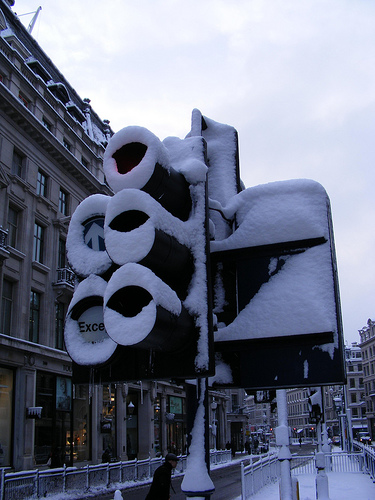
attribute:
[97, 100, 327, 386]
light — signal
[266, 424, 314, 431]
lights — red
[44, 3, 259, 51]
clouds — white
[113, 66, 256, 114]
clouds — white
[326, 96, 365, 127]
clouds — white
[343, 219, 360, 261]
clouds — white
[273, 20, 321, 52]
clouds — white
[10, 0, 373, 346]
sky — blue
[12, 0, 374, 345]
clouds — white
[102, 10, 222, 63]
clouds — white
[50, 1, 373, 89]
sky — blue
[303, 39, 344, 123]
clouds — white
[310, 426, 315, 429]
light — red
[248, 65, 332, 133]
clouds — white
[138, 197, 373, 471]
buildings — tall 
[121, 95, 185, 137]
clouds — white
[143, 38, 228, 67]
sky — blue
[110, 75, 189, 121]
clouds — white, blue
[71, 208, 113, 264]
arrow — pointing up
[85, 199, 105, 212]
snow — white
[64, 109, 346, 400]
street light — covered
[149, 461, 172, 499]
coat — black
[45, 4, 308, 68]
clouds — white 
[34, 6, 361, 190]
clouds — white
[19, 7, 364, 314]
sky — blue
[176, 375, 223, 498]
pole — black